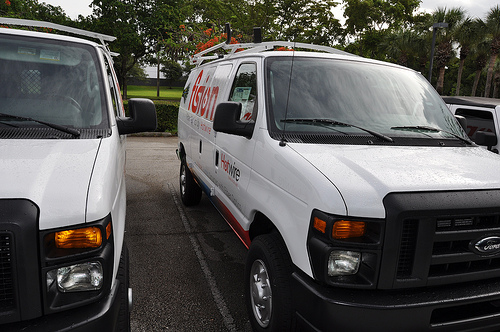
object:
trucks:
[0, 16, 160, 330]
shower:
[421, 4, 489, 29]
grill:
[393, 206, 498, 288]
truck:
[176, 23, 499, 330]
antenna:
[279, 31, 297, 146]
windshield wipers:
[280, 117, 396, 143]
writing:
[185, 70, 220, 122]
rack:
[189, 23, 360, 67]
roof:
[188, 49, 421, 72]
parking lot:
[0, 126, 499, 330]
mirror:
[209, 102, 263, 139]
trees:
[410, 7, 465, 94]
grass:
[128, 86, 158, 99]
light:
[333, 220, 369, 239]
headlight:
[325, 247, 363, 277]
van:
[172, 52, 470, 243]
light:
[344, 72, 425, 95]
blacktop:
[135, 137, 172, 193]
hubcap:
[249, 259, 273, 328]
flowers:
[200, 36, 215, 46]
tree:
[117, 2, 198, 96]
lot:
[0, 17, 498, 331]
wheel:
[246, 232, 296, 330]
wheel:
[179, 156, 204, 208]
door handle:
[214, 151, 221, 168]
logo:
[473, 235, 500, 255]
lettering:
[187, 66, 221, 122]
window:
[266, 57, 468, 138]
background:
[19, 2, 484, 120]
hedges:
[113, 98, 160, 135]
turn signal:
[314, 217, 329, 235]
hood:
[287, 142, 500, 218]